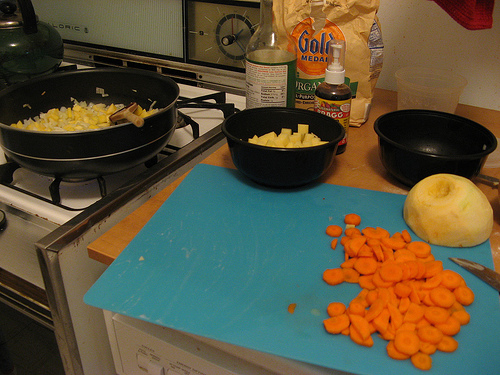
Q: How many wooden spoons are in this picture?
A: One.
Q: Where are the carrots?
A: On the cutting board.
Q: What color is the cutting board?
A: Teal.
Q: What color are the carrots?
A: Orange.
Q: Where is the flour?
A: On the counter.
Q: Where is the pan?
A: On the burner.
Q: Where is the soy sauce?
A: Behind the bowl.